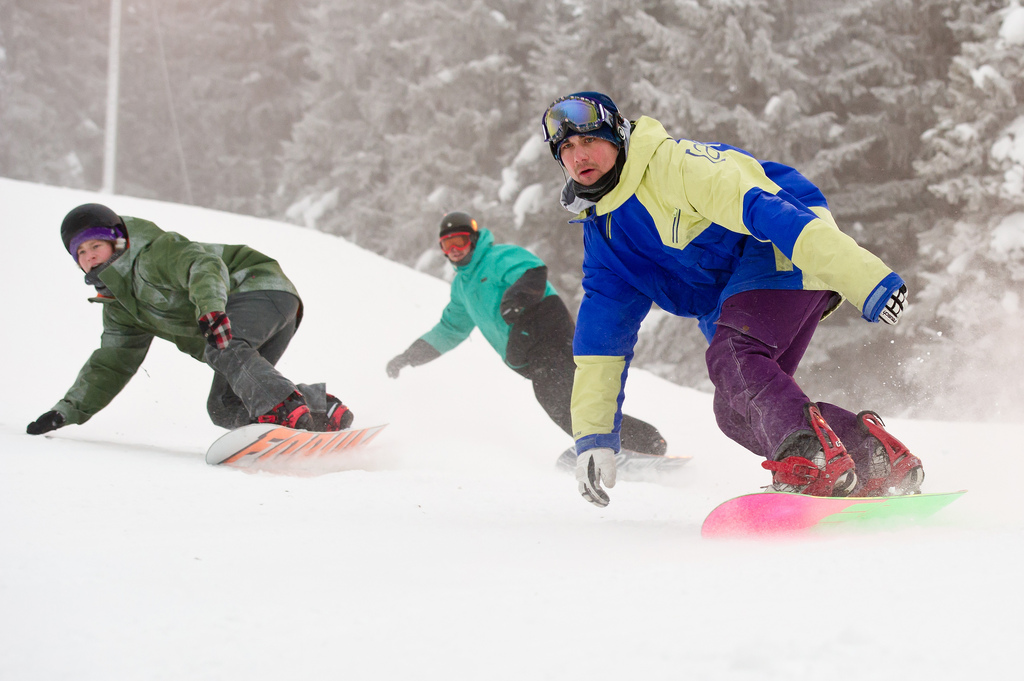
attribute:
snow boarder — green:
[29, 201, 352, 437]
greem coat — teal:
[398, 225, 559, 362]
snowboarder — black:
[564, 119, 910, 446]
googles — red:
[435, 214, 470, 234]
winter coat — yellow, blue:
[564, 135, 917, 412]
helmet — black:
[536, 83, 632, 166]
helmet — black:
[428, 212, 485, 256]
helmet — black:
[58, 197, 136, 258]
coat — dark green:
[47, 212, 305, 424]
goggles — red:
[428, 229, 485, 256]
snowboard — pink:
[687, 471, 977, 538]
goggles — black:
[533, 89, 633, 139]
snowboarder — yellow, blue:
[544, 95, 933, 497]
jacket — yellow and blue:
[538, 83, 910, 457]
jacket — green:
[406, 229, 575, 364]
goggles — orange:
[438, 214, 482, 256]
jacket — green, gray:
[48, 212, 303, 420]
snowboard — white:
[203, 407, 398, 474]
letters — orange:
[214, 415, 387, 476]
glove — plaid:
[199, 301, 236, 356]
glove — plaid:
[21, 404, 71, 430]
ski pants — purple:
[709, 284, 932, 475]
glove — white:
[572, 441, 622, 513]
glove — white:
[873, 284, 915, 330]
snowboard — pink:
[695, 476, 985, 546]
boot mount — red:
[756, 398, 878, 496]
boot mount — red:
[834, 402, 932, 496]